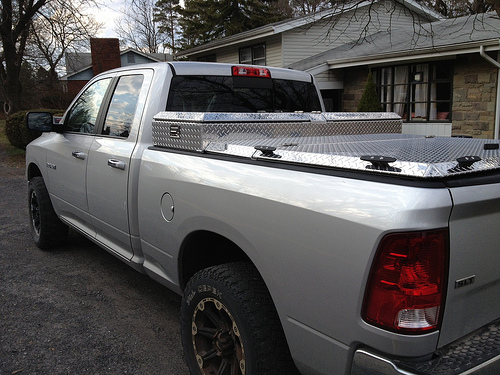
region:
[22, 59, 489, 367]
side and back of pickup truck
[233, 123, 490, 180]
metal cover on truck bed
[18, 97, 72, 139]
sideview mirror on truck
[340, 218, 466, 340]
red brakelight on truck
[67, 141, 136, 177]
two handle on doors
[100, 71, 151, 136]
reflection on car window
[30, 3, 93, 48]
trees with no leaves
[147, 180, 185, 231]
cover on gas tank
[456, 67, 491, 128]
stone wall on house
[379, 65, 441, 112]
white curtain in window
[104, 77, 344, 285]
silver colored pick-up truck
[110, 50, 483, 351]
truck in a drive way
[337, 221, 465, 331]
tail light on a truck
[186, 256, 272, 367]
black tie on a truck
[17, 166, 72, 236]
black tire on a truck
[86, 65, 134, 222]
door on truck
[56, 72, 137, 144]
windows on a truck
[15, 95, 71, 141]
black miorror on a truck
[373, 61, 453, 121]
window on a house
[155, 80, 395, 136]
tool box on a truck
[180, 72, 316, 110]
back window on a truck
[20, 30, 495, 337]
White pick-up truck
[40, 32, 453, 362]
Light gray pick-up truck.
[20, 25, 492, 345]
Pick-up truck is in front of house.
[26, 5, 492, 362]
Pick up truck in front of the house.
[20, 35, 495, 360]
White pickup truck is parked.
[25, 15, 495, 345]
Gray pickup truck is parked.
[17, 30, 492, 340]
Gray truck is parked in front of house.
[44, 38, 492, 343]
White truck is parked in front of the house.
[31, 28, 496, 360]
Truck is parked in the early morning.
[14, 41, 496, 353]
Truck has metal compartments in the back.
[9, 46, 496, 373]
"The truck is silver"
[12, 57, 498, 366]
"The truck has four doors"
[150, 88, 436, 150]
"The truck has an aluminum tool box"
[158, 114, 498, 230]
"There is an aluminum bed cover"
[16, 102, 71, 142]
"Here is a side mirror"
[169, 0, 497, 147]
"A house is here"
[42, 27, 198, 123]
"Side view of a house"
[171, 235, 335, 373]
"A tire and rim"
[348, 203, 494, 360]
"The tail light is red"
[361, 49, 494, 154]
"A house window"